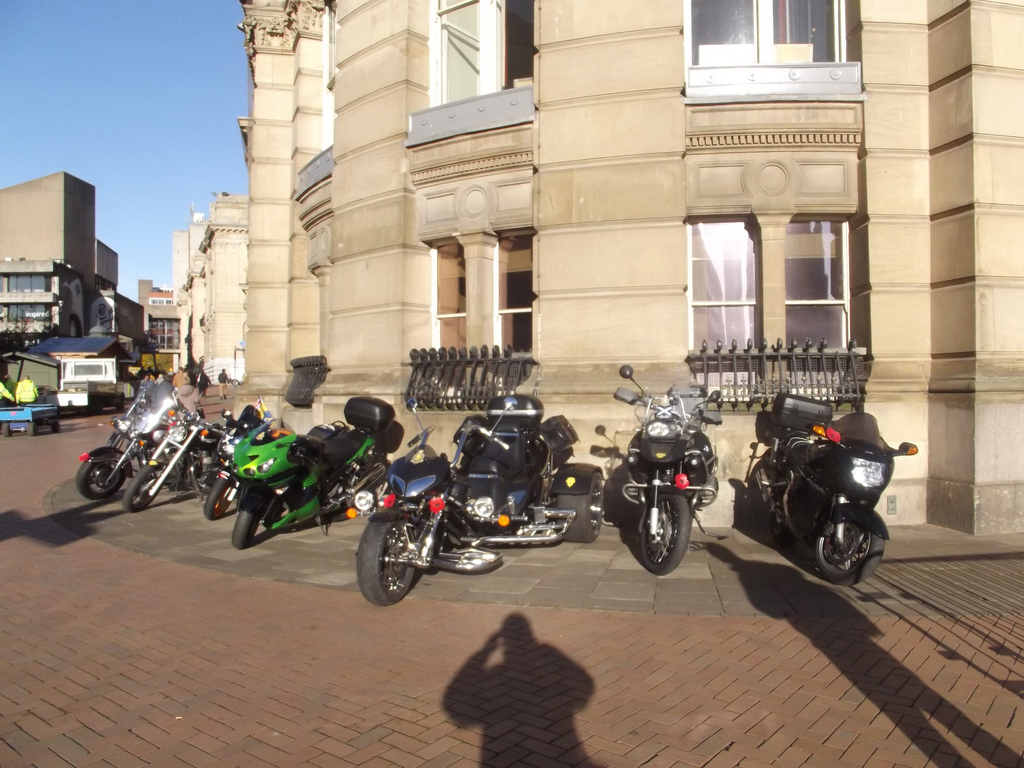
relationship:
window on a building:
[686, 213, 769, 409] [239, 3, 1020, 554]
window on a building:
[775, 207, 856, 391] [239, 3, 1020, 554]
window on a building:
[421, 234, 467, 396] [239, 3, 1020, 554]